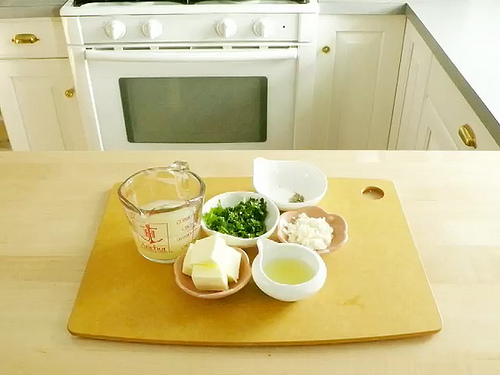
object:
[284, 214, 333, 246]
rice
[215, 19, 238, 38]
knobs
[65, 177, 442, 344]
cutting board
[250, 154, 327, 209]
bowl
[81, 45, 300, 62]
handle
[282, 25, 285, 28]
light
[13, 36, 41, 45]
handle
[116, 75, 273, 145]
window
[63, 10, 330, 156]
front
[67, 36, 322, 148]
oven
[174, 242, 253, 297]
bowl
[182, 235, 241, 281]
butter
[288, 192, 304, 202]
onion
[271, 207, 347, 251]
bowl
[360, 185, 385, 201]
hole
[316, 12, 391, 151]
door